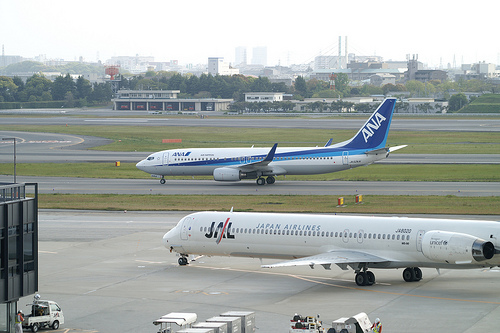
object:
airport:
[1, 108, 500, 333]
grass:
[0, 157, 497, 180]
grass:
[336, 195, 499, 215]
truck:
[20, 293, 65, 330]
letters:
[361, 127, 373, 143]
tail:
[349, 96, 396, 147]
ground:
[0, 117, 500, 333]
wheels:
[354, 271, 376, 288]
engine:
[420, 228, 495, 265]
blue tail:
[340, 97, 396, 145]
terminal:
[383, 96, 399, 106]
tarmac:
[0, 174, 500, 198]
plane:
[135, 99, 407, 188]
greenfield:
[421, 137, 451, 149]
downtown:
[0, 31, 452, 98]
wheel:
[255, 177, 266, 186]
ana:
[360, 112, 388, 143]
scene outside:
[0, 67, 500, 110]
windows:
[273, 230, 277, 236]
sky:
[0, 0, 499, 67]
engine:
[211, 168, 248, 182]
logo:
[203, 218, 236, 245]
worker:
[368, 317, 384, 332]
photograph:
[0, 0, 499, 326]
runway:
[0, 107, 499, 332]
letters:
[374, 112, 387, 127]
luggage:
[1, 175, 41, 333]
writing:
[255, 223, 281, 230]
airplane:
[160, 205, 499, 286]